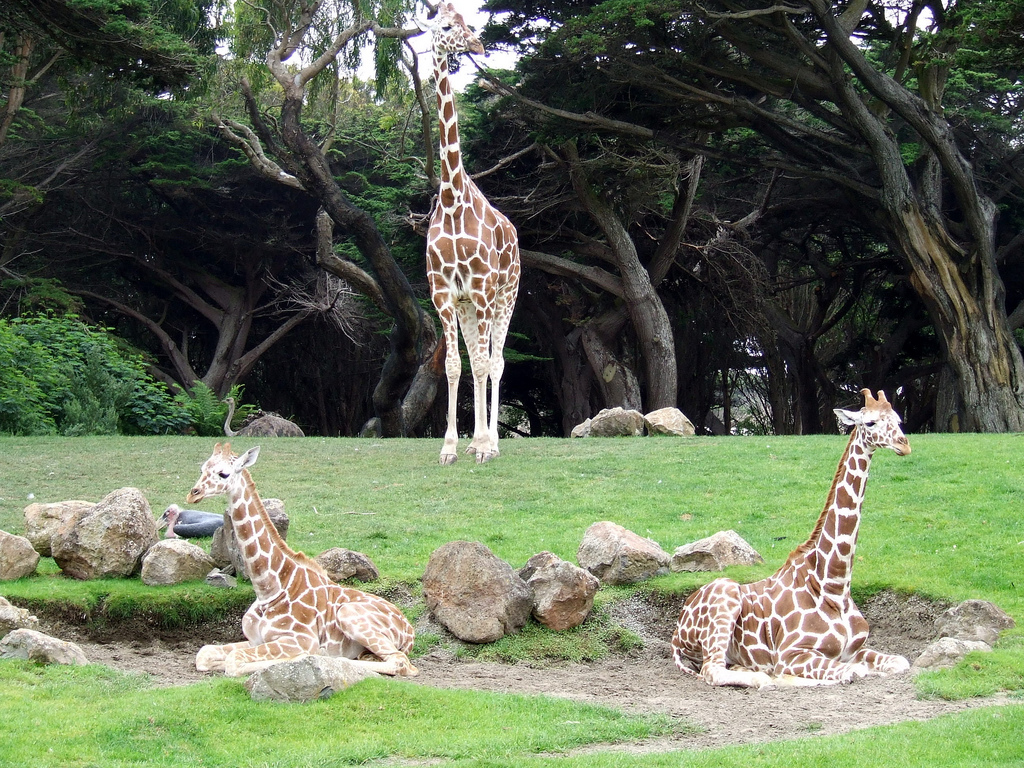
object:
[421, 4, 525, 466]
giraffe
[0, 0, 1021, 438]
woods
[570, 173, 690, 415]
branch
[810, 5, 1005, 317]
branch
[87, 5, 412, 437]
branch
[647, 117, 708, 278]
branch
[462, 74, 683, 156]
branch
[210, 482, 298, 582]
giraffe neck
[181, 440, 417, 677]
giraffe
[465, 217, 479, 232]
spot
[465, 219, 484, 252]
spot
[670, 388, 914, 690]
giraffe